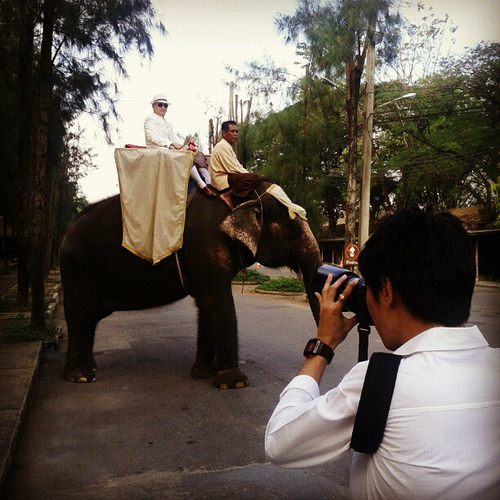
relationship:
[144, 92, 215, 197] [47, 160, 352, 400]
guy riding an elephant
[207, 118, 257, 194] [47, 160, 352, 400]
guy riding an elephant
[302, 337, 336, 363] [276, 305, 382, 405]
watch on wrist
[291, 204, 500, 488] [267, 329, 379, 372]
guy wearing watch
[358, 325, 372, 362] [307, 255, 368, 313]
strap of camera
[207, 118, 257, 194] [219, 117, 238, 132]
guy has hair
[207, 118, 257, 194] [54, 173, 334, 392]
guy sitting on elephant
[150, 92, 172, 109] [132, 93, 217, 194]
hat on man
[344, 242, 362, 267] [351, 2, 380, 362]
sign on pole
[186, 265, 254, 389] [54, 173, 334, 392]
front legs of an elephant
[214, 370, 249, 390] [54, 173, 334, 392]
foot on elephant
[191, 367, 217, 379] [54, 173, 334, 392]
foot on elephant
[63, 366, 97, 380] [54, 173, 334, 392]
foot on elephant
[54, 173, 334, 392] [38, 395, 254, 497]
elephant in road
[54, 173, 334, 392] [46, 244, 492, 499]
elephant on road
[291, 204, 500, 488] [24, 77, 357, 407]
guy taking picture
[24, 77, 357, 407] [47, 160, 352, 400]
picture of elephant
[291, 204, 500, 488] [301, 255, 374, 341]
guy holding camera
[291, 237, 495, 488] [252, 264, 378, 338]
guy using camera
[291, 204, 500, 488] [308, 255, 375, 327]
guy holding camera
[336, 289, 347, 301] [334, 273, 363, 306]
ring on finger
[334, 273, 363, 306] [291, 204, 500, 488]
finger of guy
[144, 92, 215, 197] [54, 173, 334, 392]
guy riding elephant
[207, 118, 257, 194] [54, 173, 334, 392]
guy riding elephant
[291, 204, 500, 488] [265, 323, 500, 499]
guy in shirt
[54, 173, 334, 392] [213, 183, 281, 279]
elephant has ear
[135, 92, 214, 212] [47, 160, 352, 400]
guy on elephant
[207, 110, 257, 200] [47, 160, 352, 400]
guy on elephant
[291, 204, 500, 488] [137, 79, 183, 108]
guy with hat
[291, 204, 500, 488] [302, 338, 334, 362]
guy has watch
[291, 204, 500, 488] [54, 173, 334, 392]
guy near elephant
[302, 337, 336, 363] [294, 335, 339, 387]
watch on wrist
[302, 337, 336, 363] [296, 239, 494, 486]
watch on man